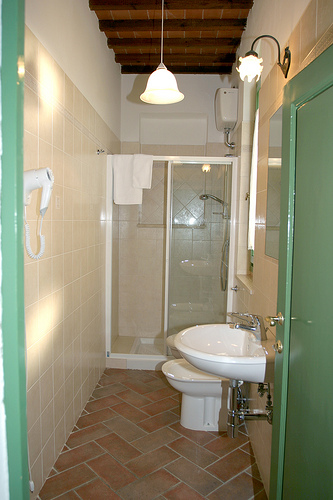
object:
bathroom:
[22, 0, 332, 499]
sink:
[174, 323, 267, 384]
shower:
[111, 160, 235, 358]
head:
[199, 193, 229, 207]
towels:
[113, 154, 153, 205]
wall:
[21, 22, 121, 499]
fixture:
[139, 0, 186, 105]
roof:
[89, 1, 254, 77]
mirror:
[264, 105, 283, 262]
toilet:
[161, 358, 231, 434]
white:
[139, 62, 185, 104]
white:
[22, 167, 55, 260]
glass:
[166, 162, 232, 338]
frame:
[108, 156, 169, 360]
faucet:
[227, 310, 267, 342]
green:
[267, 47, 332, 499]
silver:
[265, 312, 284, 328]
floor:
[37, 368, 269, 499]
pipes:
[227, 381, 273, 439]